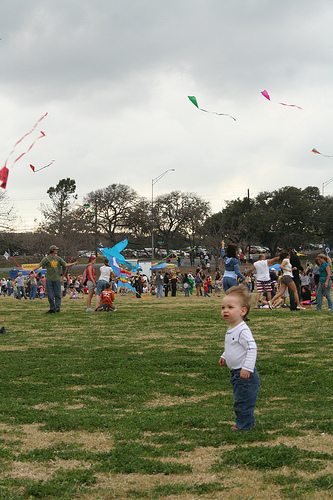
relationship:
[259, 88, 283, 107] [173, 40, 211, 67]
kite in sky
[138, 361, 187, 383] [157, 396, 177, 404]
grass on top of dirt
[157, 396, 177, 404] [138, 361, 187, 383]
dirt under grass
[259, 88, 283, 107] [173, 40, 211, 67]
kite inside sky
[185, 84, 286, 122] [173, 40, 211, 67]
kites are in sky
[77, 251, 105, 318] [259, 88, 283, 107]
man holding kite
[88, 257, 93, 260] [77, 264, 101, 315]
headband on woman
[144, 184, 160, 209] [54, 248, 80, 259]
post next to street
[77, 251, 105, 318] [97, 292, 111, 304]
man wearing shirt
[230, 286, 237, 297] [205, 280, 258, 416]
hair of toddler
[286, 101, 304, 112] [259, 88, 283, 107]
tails attached to kite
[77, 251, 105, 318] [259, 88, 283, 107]
man flying kite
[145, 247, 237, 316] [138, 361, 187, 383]
people are on grass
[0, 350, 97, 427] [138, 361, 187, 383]
field made of grass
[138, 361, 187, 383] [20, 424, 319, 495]
grass and dirt